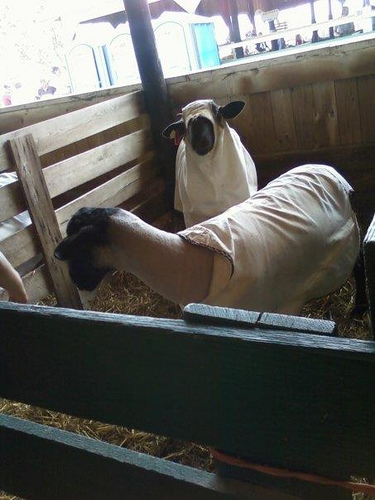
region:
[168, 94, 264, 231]
the cloth is white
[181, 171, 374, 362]
the cloth is white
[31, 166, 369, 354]
sheep wearing a cloth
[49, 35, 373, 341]
sheeps in a fence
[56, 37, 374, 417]
sheeps fenced in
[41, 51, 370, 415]
two sheeps fenced in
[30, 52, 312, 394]
two sheeps covered up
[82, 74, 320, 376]
sheeps wearing a white covering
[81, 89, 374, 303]
two sheeps wearing a white covering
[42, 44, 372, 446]
wooden fences with sheep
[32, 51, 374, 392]
an area with sheep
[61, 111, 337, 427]
sheep standing in hay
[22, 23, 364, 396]
two sheep standing on hay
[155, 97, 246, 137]
The ears of the sheep in the back.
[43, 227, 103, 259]
The ear of the sheep in the front.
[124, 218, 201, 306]
The neck of the sheep in the front.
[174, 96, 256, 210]
The white tarp over the sheep in the back.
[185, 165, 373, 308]
The white tarp covering over the sheep in the front.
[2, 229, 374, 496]
The hay the sheep are standing on.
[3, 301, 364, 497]
The green wooden posts enclosure.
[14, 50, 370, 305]
The brown wooden post enclosure.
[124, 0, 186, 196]
The tall black pole in the pen.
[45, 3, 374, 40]
The building in the background.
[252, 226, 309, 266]
Piece of cloth covering the body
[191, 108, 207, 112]
Piece of cloth covering the head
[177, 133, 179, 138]
A tag on the ear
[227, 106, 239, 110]
Ear sticking out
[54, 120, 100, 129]
A piece of the fencing plank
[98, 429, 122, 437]
Straw visible through space in planks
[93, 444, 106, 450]
Light reflecting on plank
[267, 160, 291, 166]
Shadow cast on a plank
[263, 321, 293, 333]
Horizontal and vertical plank joined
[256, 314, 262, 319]
Joint on two vertical planks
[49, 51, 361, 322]
sheep in a fence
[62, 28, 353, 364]
sheep in a fenced in area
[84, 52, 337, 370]
two sheep fenced in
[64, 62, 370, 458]
two sheeps in a fenced in area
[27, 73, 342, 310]
sheep covered in a white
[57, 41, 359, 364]
two sheep covered in white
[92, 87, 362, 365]
white covered sheep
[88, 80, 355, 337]
two white covered sheep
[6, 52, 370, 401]
a fence that is wood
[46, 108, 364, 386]
sheep standing on hay